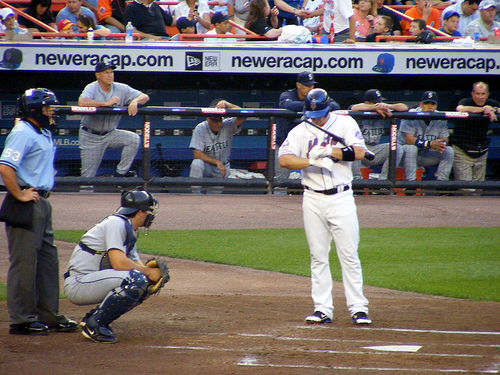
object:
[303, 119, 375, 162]
bat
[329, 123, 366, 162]
arm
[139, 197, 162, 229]
mask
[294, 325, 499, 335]
line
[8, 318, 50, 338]
man's shoe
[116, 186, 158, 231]
head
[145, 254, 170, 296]
catcher's mitt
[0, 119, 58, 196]
shirt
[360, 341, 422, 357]
home plate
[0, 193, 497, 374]
baseball field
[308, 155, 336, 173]
glove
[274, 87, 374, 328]
player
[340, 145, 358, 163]
arm band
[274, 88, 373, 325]
mets player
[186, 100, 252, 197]
players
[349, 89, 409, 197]
players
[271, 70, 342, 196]
players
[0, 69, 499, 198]
dugout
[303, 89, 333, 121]
hard helmet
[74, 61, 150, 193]
player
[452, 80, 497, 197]
player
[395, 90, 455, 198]
player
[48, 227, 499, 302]
grass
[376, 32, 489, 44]
pole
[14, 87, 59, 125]
dark helmet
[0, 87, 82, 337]
man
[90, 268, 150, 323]
pads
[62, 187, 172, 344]
player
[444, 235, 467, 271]
tree